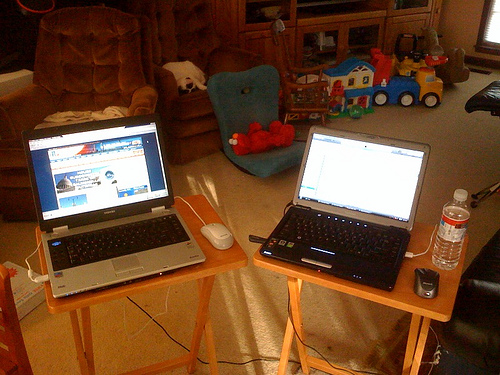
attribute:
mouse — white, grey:
[200, 219, 234, 250]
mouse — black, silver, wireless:
[413, 264, 440, 300]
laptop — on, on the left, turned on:
[20, 110, 213, 299]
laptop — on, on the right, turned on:
[256, 122, 434, 295]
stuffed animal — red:
[226, 117, 299, 161]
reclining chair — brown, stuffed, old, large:
[0, 4, 159, 223]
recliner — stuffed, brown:
[140, 0, 265, 167]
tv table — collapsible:
[252, 213, 474, 374]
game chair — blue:
[206, 62, 311, 181]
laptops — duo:
[22, 107, 433, 303]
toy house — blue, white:
[322, 55, 374, 115]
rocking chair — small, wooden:
[268, 19, 335, 124]